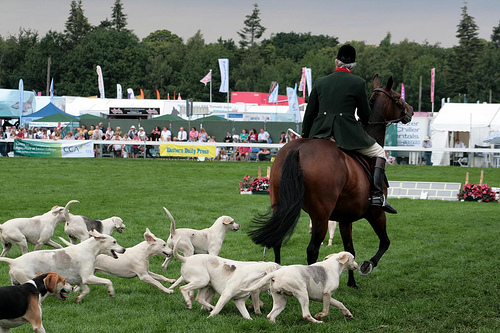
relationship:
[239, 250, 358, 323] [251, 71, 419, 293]
dog running behind horse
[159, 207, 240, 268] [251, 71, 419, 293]
dog running behind horse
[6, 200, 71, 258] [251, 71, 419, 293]
dog running behind horse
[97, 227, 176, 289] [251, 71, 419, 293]
dog running behind horse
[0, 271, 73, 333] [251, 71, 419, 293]
beagle running behind horse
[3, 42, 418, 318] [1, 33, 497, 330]
horse jocket in horsepark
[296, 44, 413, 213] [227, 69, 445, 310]
jockey riding horse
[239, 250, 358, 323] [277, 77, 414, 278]
dog running behind horse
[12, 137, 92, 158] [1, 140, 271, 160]
banners hanging over railing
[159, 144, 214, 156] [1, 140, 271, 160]
banners hanging over railing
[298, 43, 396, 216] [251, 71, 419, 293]
man riding horse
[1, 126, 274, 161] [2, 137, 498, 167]
crownd behind barrier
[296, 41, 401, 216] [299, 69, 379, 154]
jockey wearing jacket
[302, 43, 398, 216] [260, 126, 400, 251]
man on brown horse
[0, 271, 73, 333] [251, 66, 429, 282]
beagle following horse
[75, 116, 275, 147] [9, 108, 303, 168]
crownd watching sport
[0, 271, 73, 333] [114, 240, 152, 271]
beagle with fur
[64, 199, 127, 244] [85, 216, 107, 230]
dog with black spot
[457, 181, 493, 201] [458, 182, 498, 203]
flowers in bush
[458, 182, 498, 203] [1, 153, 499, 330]
bush on ground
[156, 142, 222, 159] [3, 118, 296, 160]
banner near people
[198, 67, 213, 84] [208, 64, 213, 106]
flag on pole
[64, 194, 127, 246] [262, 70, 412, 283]
dog running behind horse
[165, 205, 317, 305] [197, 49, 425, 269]
dog running behind horse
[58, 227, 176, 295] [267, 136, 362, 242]
dog running behind horse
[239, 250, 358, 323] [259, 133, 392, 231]
dog running behind horse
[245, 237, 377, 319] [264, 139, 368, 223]
dog running behind horse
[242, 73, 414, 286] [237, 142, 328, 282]
brown horse has tail